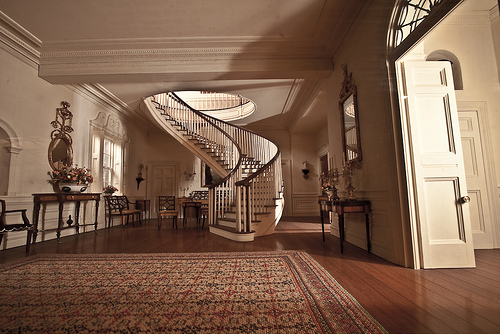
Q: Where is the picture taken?
A: A foyer.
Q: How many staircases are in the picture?
A: One.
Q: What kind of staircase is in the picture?
A: Winding staircase.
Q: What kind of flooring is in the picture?
A: Wood.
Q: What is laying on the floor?
A: A rug.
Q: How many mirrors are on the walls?
A: Two.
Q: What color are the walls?
A: White.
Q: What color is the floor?
A: Brown.